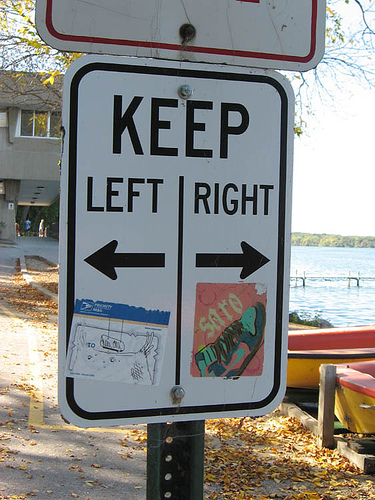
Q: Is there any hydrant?
A: No, there are no fire hydrants.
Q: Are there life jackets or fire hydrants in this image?
A: No, there are no fire hydrants or life jackets.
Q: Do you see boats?
A: Yes, there is a boat.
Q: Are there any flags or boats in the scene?
A: Yes, there is a boat.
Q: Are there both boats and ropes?
A: No, there is a boat but no ropes.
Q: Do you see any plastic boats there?
A: Yes, there is a boat that is made of plastic.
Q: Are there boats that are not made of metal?
A: Yes, there is a boat that is made of plastic.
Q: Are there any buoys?
A: No, there are no buoys.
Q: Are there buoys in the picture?
A: No, there are no buoys.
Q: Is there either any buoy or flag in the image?
A: No, there are no buoys or flags.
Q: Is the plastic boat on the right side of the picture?
A: Yes, the boat is on the right of the image.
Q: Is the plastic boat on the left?
A: No, the boat is on the right of the image.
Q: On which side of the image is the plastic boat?
A: The boat is on the right of the image.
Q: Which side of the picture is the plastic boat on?
A: The boat is on the right of the image.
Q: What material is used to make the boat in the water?
A: The boat is made of plastic.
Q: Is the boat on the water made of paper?
A: No, the boat is made of plastic.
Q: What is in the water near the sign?
A: The boat is in the water.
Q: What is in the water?
A: The boat is in the water.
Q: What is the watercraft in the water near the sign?
A: The watercraft is a boat.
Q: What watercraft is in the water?
A: The watercraft is a boat.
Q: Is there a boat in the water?
A: Yes, there is a boat in the water.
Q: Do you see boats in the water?
A: Yes, there is a boat in the water.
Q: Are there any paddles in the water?
A: No, there is a boat in the water.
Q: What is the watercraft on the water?
A: The watercraft is a boat.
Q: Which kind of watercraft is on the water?
A: The watercraft is a boat.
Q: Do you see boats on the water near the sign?
A: Yes, there is a boat on the water.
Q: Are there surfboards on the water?
A: No, there is a boat on the water.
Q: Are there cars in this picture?
A: No, there are no cars.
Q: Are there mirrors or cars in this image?
A: No, there are no cars or mirrors.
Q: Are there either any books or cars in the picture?
A: No, there are no cars or books.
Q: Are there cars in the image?
A: No, there are no cars.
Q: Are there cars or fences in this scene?
A: No, there are no cars or fences.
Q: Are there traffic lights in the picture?
A: No, there are no traffic lights.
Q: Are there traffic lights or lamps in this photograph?
A: No, there are no traffic lights or lamps.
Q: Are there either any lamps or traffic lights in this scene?
A: No, there are no traffic lights or lamps.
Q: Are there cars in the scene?
A: No, there are no cars.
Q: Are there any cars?
A: No, there are no cars.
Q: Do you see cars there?
A: No, there are no cars.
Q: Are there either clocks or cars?
A: No, there are no cars or clocks.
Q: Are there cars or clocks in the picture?
A: No, there are no cars or clocks.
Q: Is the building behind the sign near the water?
A: Yes, the building is behind the sign.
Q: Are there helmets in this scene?
A: No, there are no helmets.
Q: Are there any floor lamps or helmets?
A: No, there are no helmets or floor lamps.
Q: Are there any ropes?
A: No, there are no ropes.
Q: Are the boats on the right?
A: Yes, the boats are on the right of the image.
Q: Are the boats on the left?
A: No, the boats are on the right of the image.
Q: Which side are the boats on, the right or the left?
A: The boats are on the right of the image.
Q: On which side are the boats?
A: The boats are on the right of the image.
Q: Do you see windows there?
A: Yes, there is a window.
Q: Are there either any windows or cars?
A: Yes, there is a window.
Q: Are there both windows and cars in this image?
A: No, there is a window but no cars.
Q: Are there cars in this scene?
A: No, there are no cars.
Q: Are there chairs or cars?
A: No, there are no cars or chairs.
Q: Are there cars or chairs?
A: No, there are no cars or chairs.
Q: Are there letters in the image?
A: Yes, there are letters.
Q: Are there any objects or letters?
A: Yes, there are letters.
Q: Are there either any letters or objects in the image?
A: Yes, there are letters.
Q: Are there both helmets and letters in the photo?
A: No, there are letters but no helmets.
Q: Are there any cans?
A: No, there are no cans.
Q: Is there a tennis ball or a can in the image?
A: No, there are no cans or tennis balls.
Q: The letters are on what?
A: The letters are on the sign.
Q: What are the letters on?
A: The letters are on the sign.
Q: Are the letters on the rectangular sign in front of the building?
A: Yes, the letters are on the sign.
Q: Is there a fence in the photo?
A: No, there are no fences.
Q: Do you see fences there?
A: No, there are no fences.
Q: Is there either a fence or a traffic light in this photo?
A: No, there are no fences or traffic lights.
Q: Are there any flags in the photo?
A: No, there are no flags.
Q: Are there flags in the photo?
A: No, there are no flags.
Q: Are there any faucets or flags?
A: No, there are no flags or faucets.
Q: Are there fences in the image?
A: No, there are no fences.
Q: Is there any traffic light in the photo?
A: No, there are no traffic lights.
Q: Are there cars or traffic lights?
A: No, there are no traffic lights or cars.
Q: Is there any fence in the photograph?
A: No, there are no fences.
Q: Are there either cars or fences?
A: No, there are no fences or cars.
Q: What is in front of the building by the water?
A: The sign is in front of the building.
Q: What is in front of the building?
A: The sign is in front of the building.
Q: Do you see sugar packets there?
A: No, there are no sugar packets.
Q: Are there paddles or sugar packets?
A: No, there are no sugar packets or paddles.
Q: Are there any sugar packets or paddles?
A: No, there are no sugar packets or paddles.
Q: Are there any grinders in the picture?
A: No, there are no grinders.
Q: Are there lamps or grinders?
A: No, there are no grinders or lamps.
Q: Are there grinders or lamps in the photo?
A: No, there are no grinders or lamps.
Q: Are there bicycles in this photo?
A: No, there are no bicycles.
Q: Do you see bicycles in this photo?
A: No, there are no bicycles.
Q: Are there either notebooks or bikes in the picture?
A: No, there are no bikes or notebooks.